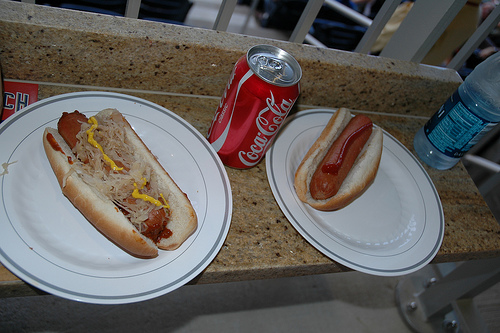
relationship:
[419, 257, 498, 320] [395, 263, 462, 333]
leg has base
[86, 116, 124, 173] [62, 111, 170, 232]
mustard on sauerkraut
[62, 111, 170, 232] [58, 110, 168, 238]
sauerkraut on hot dog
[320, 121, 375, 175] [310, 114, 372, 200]
ketchup on hot dog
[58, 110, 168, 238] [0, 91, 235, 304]
hot dog on plate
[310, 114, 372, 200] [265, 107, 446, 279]
hot dog on plate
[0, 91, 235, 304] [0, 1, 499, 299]
plate on counter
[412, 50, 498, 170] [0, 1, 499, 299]
bottle on counter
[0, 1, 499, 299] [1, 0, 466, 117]
counter has ledge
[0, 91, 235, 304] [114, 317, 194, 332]
plate has shadow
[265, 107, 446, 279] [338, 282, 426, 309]
plate has shadow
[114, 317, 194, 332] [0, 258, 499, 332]
shadow on floor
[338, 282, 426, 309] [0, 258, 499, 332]
shadow on floor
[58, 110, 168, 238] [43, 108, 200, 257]
hot dog on bun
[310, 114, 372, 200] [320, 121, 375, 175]
hot dog has ketchup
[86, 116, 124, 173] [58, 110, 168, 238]
mustard on hot dog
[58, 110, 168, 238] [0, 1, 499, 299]
hot dog on counter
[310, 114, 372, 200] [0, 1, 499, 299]
hot dog on counter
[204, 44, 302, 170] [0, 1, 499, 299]
can on counter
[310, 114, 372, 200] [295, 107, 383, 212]
hot dog on bun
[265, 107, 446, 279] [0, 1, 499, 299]
plate on counter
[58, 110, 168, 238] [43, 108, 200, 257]
hot dog in a bun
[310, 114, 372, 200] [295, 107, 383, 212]
hot dog in a bun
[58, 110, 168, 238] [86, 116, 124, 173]
hot dog has mustard